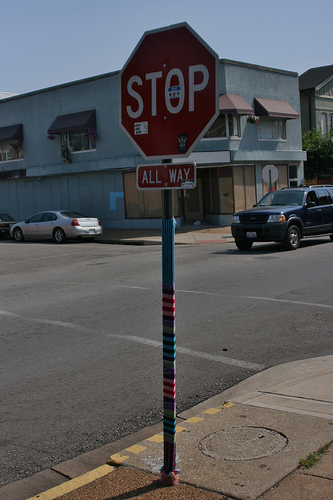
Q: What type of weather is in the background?
A: It is clear.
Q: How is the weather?
A: It is clear.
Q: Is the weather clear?
A: Yes, it is clear.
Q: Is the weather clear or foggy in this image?
A: It is clear.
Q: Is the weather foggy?
A: No, it is clear.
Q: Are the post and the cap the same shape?
A: Yes, both the post and the cap are round.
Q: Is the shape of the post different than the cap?
A: No, both the post and the cap are round.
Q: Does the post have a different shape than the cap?
A: No, both the post and the cap are round.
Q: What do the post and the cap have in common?
A: The shape, both the post and the cap are round.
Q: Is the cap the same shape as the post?
A: Yes, both the cap and the post are round.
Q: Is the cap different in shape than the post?
A: No, both the cap and the post are round.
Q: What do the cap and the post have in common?
A: The shape, both the cap and the post are round.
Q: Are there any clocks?
A: No, there are no clocks.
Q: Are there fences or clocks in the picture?
A: No, there are no clocks or fences.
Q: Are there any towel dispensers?
A: No, there are no towel dispensers.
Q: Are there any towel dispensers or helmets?
A: No, there are no towel dispensers or helmets.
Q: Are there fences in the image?
A: No, there are no fences.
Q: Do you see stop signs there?
A: Yes, there is a stop sign.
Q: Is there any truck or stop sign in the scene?
A: Yes, there is a stop sign.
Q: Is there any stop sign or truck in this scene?
A: Yes, there is a stop sign.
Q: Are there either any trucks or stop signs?
A: Yes, there is a stop sign.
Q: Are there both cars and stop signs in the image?
A: Yes, there are both a stop sign and a car.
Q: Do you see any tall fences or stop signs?
A: Yes, there is a tall stop sign.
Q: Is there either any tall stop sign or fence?
A: Yes, there is a tall stop sign.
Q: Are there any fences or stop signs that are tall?
A: Yes, the stop sign is tall.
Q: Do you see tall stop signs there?
A: Yes, there is a tall stop sign.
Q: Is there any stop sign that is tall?
A: Yes, there is a stop sign that is tall.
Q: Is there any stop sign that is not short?
A: Yes, there is a tall stop sign.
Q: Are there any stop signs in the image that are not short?
A: Yes, there is a tall stop sign.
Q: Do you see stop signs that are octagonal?
A: Yes, there is an octagonal stop sign.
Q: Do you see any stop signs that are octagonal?
A: Yes, there is a stop sign that is octagonal.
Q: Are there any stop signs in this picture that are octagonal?
A: Yes, there is a stop sign that is octagonal.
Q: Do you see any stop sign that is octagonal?
A: Yes, there is a stop sign that is octagonal.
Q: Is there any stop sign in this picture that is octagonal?
A: Yes, there is a stop sign that is octagonal.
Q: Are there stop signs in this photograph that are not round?
A: Yes, there is a octagonal stop sign.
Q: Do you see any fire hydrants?
A: No, there are no fire hydrants.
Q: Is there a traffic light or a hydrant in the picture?
A: No, there are no fire hydrants or traffic lights.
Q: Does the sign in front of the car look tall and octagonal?
A: Yes, the stop sign is tall and octagonal.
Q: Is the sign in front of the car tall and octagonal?
A: Yes, the stop sign is tall and octagonal.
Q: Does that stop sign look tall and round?
A: No, the stop sign is tall but octagonal.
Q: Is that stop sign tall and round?
A: No, the stop sign is tall but octagonal.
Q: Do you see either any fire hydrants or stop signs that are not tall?
A: No, there is a stop sign but it is tall.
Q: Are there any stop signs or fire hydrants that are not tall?
A: No, there is a stop sign but it is tall.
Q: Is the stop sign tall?
A: Yes, the stop sign is tall.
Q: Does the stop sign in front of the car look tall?
A: Yes, the stop sign is tall.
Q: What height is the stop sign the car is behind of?
A: The stop sign is tall.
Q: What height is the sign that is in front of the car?
A: The stop sign is tall.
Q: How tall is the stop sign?
A: The stop sign is tall.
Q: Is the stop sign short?
A: No, the stop sign is tall.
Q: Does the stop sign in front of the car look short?
A: No, the stop sign is tall.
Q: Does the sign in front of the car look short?
A: No, the stop sign is tall.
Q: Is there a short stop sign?
A: No, there is a stop sign but it is tall.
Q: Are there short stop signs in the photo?
A: No, there is a stop sign but it is tall.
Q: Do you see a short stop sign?
A: No, there is a stop sign but it is tall.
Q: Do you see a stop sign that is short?
A: No, there is a stop sign but it is tall.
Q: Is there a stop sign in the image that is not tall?
A: No, there is a stop sign but it is tall.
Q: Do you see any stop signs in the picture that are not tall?
A: No, there is a stop sign but it is tall.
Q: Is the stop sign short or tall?
A: The stop sign is tall.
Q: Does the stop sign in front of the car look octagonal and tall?
A: Yes, the stop sign is octagonal and tall.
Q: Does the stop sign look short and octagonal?
A: No, the stop sign is octagonal but tall.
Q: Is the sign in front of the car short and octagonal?
A: No, the stop sign is octagonal but tall.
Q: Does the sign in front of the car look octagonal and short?
A: No, the stop sign is octagonal but tall.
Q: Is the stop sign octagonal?
A: Yes, the stop sign is octagonal.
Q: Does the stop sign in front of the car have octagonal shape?
A: Yes, the stop sign is octagonal.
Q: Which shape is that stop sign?
A: The stop sign is octagonal.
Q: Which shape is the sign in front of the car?
A: The stop sign is octagonal.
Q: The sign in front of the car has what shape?
A: The stop sign is octagonal.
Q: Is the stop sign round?
A: No, the stop sign is octagonal.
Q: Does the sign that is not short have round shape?
A: No, the stop sign is octagonal.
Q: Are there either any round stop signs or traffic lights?
A: No, there is a stop sign but it is octagonal.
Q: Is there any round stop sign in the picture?
A: No, there is a stop sign but it is octagonal.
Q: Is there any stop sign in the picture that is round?
A: No, there is a stop sign but it is octagonal.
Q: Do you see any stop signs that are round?
A: No, there is a stop sign but it is octagonal.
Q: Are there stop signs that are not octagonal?
A: No, there is a stop sign but it is octagonal.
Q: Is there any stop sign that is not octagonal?
A: No, there is a stop sign but it is octagonal.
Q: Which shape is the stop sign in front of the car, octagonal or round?
A: The stop sign is octagonal.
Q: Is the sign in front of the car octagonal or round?
A: The stop sign is octagonal.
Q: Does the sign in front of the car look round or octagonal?
A: The stop sign is octagonal.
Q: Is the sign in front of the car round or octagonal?
A: The stop sign is octagonal.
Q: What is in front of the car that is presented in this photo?
A: The stop sign is in front of the car.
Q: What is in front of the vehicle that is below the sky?
A: The stop sign is in front of the car.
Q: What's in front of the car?
A: The stop sign is in front of the car.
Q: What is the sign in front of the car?
A: The sign is a stop sign.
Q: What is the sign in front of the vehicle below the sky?
A: The sign is a stop sign.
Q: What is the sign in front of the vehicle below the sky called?
A: The sign is a stop sign.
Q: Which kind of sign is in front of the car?
A: The sign is a stop sign.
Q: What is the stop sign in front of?
A: The stop sign is in front of the car.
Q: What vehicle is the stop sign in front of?
A: The stop sign is in front of the car.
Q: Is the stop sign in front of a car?
A: Yes, the stop sign is in front of a car.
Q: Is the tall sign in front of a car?
A: Yes, the stop sign is in front of a car.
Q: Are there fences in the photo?
A: No, there are no fences.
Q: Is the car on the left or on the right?
A: The car is on the left of the image.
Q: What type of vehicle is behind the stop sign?
A: The vehicle is a car.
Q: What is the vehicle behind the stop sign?
A: The vehicle is a car.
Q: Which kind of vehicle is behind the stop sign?
A: The vehicle is a car.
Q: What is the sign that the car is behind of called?
A: The sign is a stop sign.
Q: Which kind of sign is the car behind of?
A: The car is behind the stop sign.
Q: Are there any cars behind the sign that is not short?
A: Yes, there is a car behind the stop sign.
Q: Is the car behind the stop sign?
A: Yes, the car is behind the stop sign.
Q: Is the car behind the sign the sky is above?
A: Yes, the car is behind the stop sign.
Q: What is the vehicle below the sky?
A: The vehicle is a car.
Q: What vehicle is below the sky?
A: The vehicle is a car.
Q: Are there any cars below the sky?
A: Yes, there is a car below the sky.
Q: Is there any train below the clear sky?
A: No, there is a car below the sky.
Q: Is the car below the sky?
A: Yes, the car is below the sky.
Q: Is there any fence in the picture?
A: No, there are no fences.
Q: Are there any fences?
A: No, there are no fences.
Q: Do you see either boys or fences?
A: No, there are no fences or boys.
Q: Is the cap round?
A: Yes, the cap is round.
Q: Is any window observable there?
A: Yes, there is a window.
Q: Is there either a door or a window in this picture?
A: Yes, there is a window.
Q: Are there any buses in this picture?
A: No, there are no buses.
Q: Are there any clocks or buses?
A: No, there are no buses or clocks.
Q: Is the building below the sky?
A: Yes, the building is below the sky.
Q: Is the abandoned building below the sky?
A: Yes, the building is below the sky.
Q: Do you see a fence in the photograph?
A: No, there are no fences.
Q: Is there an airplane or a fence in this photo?
A: No, there are no fences or airplanes.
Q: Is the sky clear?
A: Yes, the sky is clear.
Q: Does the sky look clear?
A: Yes, the sky is clear.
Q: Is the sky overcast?
A: No, the sky is clear.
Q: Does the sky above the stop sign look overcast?
A: No, the sky is clear.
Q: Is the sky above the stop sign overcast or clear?
A: The sky is clear.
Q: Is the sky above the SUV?
A: Yes, the sky is above the SUV.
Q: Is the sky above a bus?
A: No, the sky is above the SUV.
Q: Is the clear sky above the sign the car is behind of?
A: Yes, the sky is above the stop sign.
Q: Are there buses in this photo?
A: No, there are no buses.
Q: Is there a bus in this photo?
A: No, there are no buses.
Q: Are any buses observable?
A: No, there are no buses.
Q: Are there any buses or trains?
A: No, there are no buses or trains.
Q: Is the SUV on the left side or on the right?
A: The SUV is on the right of the image.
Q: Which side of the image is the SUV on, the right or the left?
A: The SUV is on the right of the image.